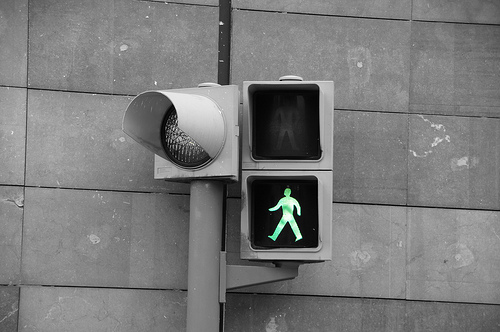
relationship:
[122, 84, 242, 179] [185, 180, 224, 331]
light on pole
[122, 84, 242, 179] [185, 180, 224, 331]
light on a pole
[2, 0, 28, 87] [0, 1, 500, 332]
block on a wall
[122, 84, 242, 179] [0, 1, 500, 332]
light on a wall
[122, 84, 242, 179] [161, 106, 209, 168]
light has lens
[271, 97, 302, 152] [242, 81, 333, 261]
man on sign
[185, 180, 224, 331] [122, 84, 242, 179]
pole holding light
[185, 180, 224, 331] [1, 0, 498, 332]
pole on building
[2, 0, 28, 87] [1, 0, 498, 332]
block on building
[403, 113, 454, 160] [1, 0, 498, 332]
stain on building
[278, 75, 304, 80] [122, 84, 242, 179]
knob on light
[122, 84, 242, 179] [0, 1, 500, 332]
light by wall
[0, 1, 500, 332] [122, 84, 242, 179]
wall behind light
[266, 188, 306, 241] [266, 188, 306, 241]
symbol not lighted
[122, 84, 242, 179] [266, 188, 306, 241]
light for stop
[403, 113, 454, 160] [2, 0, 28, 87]
mark on brick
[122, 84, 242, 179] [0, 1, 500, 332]
light against wall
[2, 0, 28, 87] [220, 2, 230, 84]
block has line